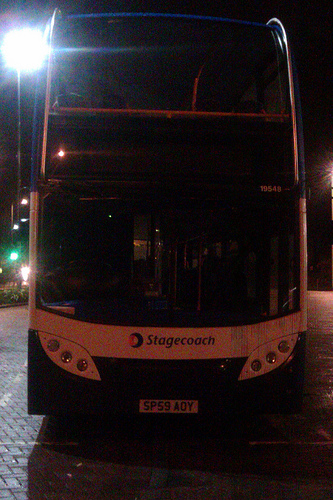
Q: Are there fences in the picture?
A: No, there are no fences.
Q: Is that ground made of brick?
A: Yes, the ground is made of brick.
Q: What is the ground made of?
A: The ground is made of brick.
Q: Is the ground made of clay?
A: No, the ground is made of brick.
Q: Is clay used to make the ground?
A: No, the ground is made of brick.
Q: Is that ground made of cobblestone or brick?
A: The ground is made of brick.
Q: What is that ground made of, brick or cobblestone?
A: The ground is made of brick.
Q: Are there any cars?
A: No, there are no cars.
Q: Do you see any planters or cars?
A: No, there are no cars or planters.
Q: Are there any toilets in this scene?
A: No, there are no toilets.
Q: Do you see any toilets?
A: No, there are no toilets.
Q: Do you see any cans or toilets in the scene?
A: No, there are no toilets or cans.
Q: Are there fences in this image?
A: No, there are no fences.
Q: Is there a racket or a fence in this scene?
A: No, there are no fences or rackets.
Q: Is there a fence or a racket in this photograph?
A: No, there are no fences or rackets.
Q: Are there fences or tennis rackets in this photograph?
A: No, there are no fences or tennis rackets.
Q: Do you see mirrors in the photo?
A: No, there are no mirrors.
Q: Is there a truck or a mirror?
A: No, there are no mirrors or trucks.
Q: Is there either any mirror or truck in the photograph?
A: No, there are no mirrors or trucks.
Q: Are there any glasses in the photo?
A: No, there are no glasses.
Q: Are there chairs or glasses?
A: No, there are no glasses or chairs.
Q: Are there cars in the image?
A: No, there are no cars.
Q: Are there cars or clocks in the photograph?
A: No, there are no cars or clocks.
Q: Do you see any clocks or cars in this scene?
A: No, there are no cars or clocks.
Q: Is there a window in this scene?
A: Yes, there is a window.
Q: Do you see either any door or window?
A: Yes, there is a window.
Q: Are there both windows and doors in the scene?
A: No, there is a window but no doors.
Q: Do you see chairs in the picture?
A: No, there are no chairs.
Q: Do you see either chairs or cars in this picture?
A: No, there are no chairs or cars.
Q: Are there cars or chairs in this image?
A: No, there are no chairs or cars.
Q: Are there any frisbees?
A: No, there are no frisbees.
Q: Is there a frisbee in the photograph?
A: No, there are no frisbees.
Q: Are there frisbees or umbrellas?
A: No, there are no frisbees or umbrellas.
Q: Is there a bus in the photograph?
A: Yes, there is a bus.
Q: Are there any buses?
A: Yes, there is a bus.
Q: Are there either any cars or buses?
A: Yes, there is a bus.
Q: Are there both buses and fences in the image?
A: No, there is a bus but no fences.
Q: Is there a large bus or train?
A: Yes, there is a large bus.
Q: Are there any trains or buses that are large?
A: Yes, the bus is large.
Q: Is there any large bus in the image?
A: Yes, there is a large bus.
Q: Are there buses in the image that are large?
A: Yes, there is a bus that is large.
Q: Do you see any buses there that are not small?
A: Yes, there is a large bus.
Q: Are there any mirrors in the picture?
A: No, there are no mirrors.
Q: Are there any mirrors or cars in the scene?
A: No, there are no mirrors or cars.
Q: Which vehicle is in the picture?
A: The vehicle is a bus.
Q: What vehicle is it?
A: The vehicle is a bus.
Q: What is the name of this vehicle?
A: This is a bus.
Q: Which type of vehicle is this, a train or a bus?
A: This is a bus.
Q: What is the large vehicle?
A: The vehicle is a bus.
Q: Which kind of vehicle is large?
A: The vehicle is a bus.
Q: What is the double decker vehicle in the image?
A: The vehicle is a bus.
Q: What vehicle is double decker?
A: The vehicle is a bus.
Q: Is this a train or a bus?
A: This is a bus.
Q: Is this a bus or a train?
A: This is a bus.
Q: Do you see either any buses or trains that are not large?
A: No, there is a bus but it is large.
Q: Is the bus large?
A: Yes, the bus is large.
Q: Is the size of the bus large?
A: Yes, the bus is large.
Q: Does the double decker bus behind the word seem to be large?
A: Yes, the bus is large.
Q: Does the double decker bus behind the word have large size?
A: Yes, the bus is large.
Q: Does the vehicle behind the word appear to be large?
A: Yes, the bus is large.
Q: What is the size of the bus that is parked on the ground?
A: The bus is large.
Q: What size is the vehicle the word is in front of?
A: The bus is large.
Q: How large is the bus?
A: The bus is large.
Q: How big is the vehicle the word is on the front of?
A: The bus is large.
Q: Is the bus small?
A: No, the bus is large.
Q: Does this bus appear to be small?
A: No, the bus is large.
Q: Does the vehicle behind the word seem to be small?
A: No, the bus is large.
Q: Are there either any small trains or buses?
A: No, there is a bus but it is large.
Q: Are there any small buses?
A: No, there is a bus but it is large.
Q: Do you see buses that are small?
A: No, there is a bus but it is large.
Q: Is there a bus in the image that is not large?
A: No, there is a bus but it is large.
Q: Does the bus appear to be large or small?
A: The bus is large.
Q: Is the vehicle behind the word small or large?
A: The bus is large.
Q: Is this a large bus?
A: Yes, this is a large bus.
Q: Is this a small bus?
A: No, this is a large bus.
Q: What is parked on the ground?
A: The bus is parked on the ground.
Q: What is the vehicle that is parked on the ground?
A: The vehicle is a bus.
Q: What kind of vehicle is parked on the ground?
A: The vehicle is a bus.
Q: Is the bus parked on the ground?
A: Yes, the bus is parked on the ground.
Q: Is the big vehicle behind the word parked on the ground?
A: Yes, the bus is parked on the ground.